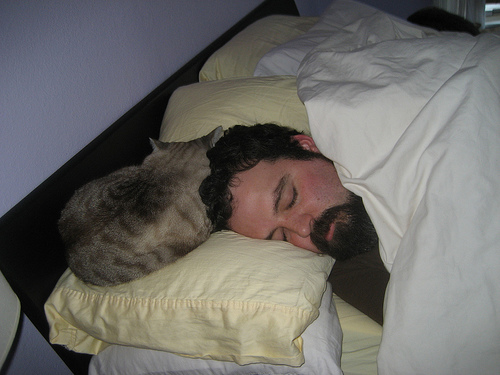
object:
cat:
[58, 125, 225, 287]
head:
[198, 118, 378, 263]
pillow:
[43, 72, 338, 367]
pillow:
[198, 14, 320, 84]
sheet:
[251, 2, 500, 374]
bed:
[0, 0, 499, 374]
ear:
[293, 134, 320, 154]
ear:
[205, 125, 224, 149]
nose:
[278, 213, 315, 238]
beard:
[309, 190, 379, 262]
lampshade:
[0, 270, 25, 374]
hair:
[198, 121, 314, 231]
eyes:
[265, 172, 300, 242]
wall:
[0, 0, 305, 375]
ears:
[149, 125, 224, 150]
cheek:
[300, 159, 346, 209]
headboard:
[1, 0, 303, 374]